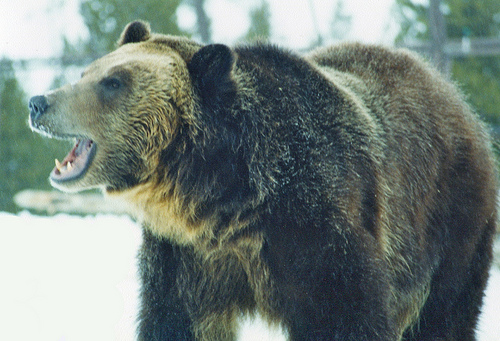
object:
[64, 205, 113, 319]
snow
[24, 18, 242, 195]
head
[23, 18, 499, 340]
bear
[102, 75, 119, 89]
eye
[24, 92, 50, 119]
nose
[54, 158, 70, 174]
teeth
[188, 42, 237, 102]
ear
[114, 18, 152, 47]
ear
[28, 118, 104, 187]
mouth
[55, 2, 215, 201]
trees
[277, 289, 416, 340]
leg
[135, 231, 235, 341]
leg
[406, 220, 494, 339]
leg